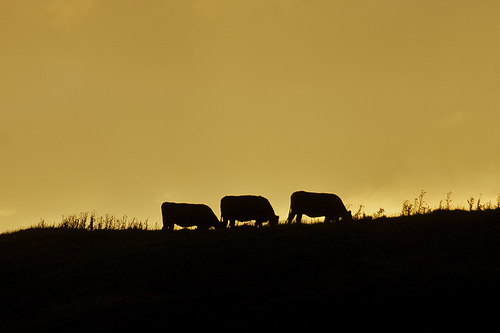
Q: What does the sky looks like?
A: Golden sky.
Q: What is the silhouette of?
A: Three animal.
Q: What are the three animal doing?
A: Grazing.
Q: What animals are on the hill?
A: Cows.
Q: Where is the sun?
A: Setting behind the hill.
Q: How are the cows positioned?
A: In a line.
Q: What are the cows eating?
A: Grass.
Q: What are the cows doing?
A: Eating.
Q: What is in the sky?
A: Clouds.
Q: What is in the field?
A: Three cows.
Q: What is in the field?
A: Three cows.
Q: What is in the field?
A: Three cows.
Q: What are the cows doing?
A: Grazing together.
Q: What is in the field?
A: Darkness.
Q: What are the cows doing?
A: Grazing.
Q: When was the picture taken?
A: Sunset.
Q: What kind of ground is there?
A: Grass.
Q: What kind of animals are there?
A: Cows.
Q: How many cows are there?
A: Three.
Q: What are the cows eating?
A: Grass.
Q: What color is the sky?
A: Gold.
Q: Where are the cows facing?
A: To the right.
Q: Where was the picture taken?
A: In the pasture.